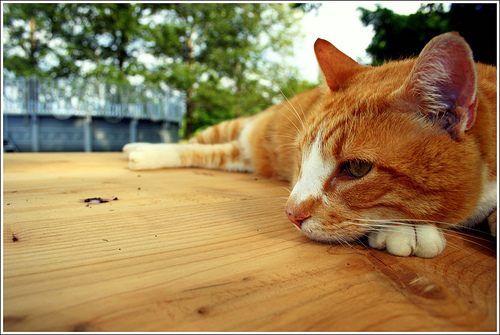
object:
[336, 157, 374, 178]
eye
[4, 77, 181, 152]
above ground pool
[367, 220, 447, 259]
foot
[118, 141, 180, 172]
foot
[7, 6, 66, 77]
shade tree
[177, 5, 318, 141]
shade tree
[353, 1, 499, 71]
shade tree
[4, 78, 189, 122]
fence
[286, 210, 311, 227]
nose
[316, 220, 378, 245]
mouth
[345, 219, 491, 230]
whiskers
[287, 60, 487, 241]
head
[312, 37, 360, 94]
ear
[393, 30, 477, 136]
ear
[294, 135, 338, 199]
spot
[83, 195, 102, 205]
debris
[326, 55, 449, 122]
hair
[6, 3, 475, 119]
sky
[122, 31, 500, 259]
cat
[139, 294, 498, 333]
table